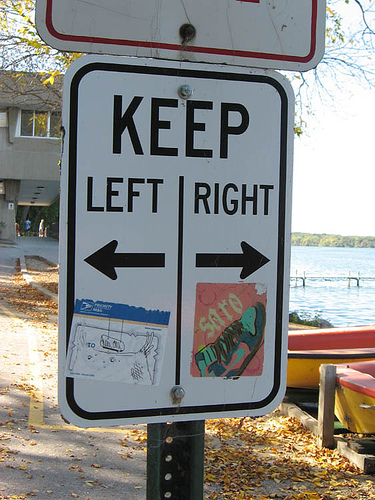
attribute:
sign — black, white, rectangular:
[42, 41, 304, 422]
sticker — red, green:
[180, 273, 277, 391]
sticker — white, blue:
[62, 288, 172, 402]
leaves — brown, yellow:
[202, 411, 360, 497]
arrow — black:
[189, 241, 274, 284]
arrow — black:
[82, 230, 176, 285]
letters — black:
[84, 88, 281, 233]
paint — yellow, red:
[286, 352, 370, 387]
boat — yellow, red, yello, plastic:
[291, 321, 373, 385]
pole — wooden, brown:
[311, 354, 343, 453]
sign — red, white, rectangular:
[28, 3, 328, 73]